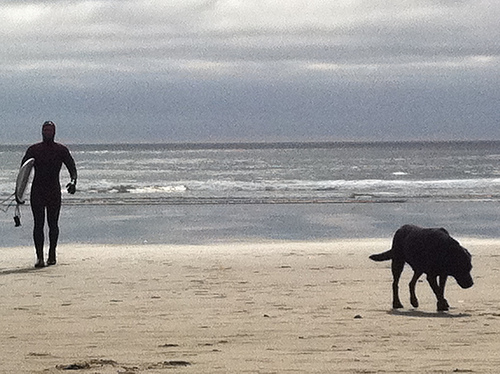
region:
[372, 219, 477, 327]
dog is walking on the sand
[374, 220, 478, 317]
dog is black in color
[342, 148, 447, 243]
water is behind the dog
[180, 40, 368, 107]
sky is cloudy and gray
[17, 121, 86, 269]
person is out of the water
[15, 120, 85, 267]
person is walking on the beach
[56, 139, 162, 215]
water is behind the person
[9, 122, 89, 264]
person is holding a surfboard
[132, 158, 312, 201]
water has small waves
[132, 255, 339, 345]
sand is brownish gray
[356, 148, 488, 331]
a dog in front the beach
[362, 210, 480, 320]
the dog is black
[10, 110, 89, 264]
the surfer is wet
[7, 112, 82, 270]
the surfer has a surfboard under right arm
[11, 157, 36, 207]
surfboard is color white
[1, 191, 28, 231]
the rope of a surfboard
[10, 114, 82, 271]
man wears a black suit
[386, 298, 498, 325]
a shadow on the sand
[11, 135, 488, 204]
small waves in the ocean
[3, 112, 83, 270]
surfer wears a black wetsuit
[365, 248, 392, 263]
The tail of the dog.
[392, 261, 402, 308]
The back left leg of the dog.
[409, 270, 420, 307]
The back right leg of the dog.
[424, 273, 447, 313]
The front left leg of the dog.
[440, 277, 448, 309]
The front right leg of the dog.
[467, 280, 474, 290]
The nose area of the dog.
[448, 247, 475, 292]
The head of the dog.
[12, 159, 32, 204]
The surfboard the surfer is carrying.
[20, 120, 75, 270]
The wet suit the surfer is wearing.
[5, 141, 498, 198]
The water in the distance.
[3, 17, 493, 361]
Photo taken at the beach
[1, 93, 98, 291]
man in a wet suit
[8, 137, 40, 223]
Surfboard under the man's arm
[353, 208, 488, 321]
The dog is black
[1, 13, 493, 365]
Photo taken during the day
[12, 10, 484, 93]
Clouds in the sky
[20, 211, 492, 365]
The sand is brown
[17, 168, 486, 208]
White cap on the wave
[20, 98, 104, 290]
Man walking on the beach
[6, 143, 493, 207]
The waves aren't large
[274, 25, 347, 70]
this is the sky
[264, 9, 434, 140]
the sky is full of clouds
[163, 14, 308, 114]
the sky is bright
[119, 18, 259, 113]
the clouds are white in color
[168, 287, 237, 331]
this is the ground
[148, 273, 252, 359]
the ground is sandy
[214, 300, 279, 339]
the sand is brown in color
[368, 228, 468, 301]
this is a dog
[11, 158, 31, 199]
this is a surfboard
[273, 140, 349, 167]
this is the water